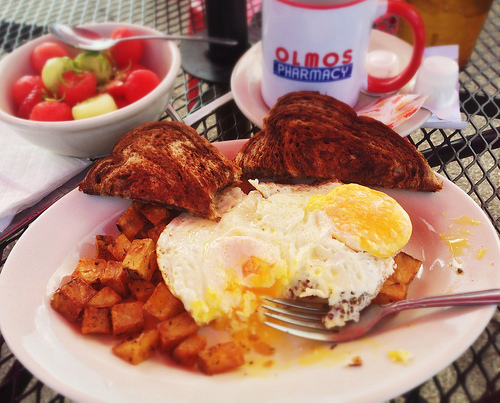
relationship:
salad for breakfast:
[13, 25, 149, 125] [55, 121, 438, 351]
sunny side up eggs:
[157, 212, 347, 304] [178, 182, 392, 322]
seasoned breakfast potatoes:
[69, 226, 205, 358] [182, 304, 262, 384]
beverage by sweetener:
[256, 6, 398, 104] [350, 83, 425, 122]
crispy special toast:
[90, 138, 230, 200] [278, 93, 412, 185]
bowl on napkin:
[6, 62, 136, 146] [6, 135, 56, 209]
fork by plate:
[276, 290, 498, 324] [0, 123, 496, 397]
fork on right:
[276, 290, 498, 324] [303, 279, 494, 300]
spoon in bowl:
[48, 12, 249, 60] [6, 62, 136, 146]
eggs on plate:
[178, 182, 392, 322] [0, 123, 496, 397]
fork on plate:
[276, 290, 498, 324] [0, 123, 496, 397]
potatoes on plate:
[182, 304, 262, 384] [0, 123, 496, 397]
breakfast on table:
[55, 121, 438, 351] [475, 46, 498, 117]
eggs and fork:
[178, 182, 392, 322] [276, 290, 498, 324]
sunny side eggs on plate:
[157, 212, 347, 304] [0, 123, 496, 397]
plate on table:
[0, 123, 496, 397] [475, 46, 498, 117]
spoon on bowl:
[48, 12, 249, 60] [6, 62, 136, 146]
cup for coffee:
[274, 3, 469, 86] [266, 11, 350, 78]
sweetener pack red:
[350, 83, 425, 122] [395, 2, 433, 77]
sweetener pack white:
[350, 83, 425, 122] [266, 22, 352, 41]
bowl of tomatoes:
[6, 62, 136, 146] [20, 59, 77, 122]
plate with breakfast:
[0, 123, 496, 397] [55, 121, 438, 351]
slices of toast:
[92, 108, 423, 183] [278, 93, 412, 185]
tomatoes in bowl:
[20, 59, 77, 122] [6, 62, 136, 146]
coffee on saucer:
[266, 11, 350, 78] [235, 59, 273, 115]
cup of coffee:
[274, 3, 469, 86] [266, 11, 350, 78]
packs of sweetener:
[352, 97, 436, 135] [350, 83, 425, 122]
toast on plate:
[278, 93, 412, 185] [0, 123, 496, 397]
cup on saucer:
[274, 3, 469, 86] [235, 59, 273, 115]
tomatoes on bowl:
[20, 59, 77, 122] [6, 62, 136, 146]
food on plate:
[55, 121, 438, 351] [0, 123, 496, 397]